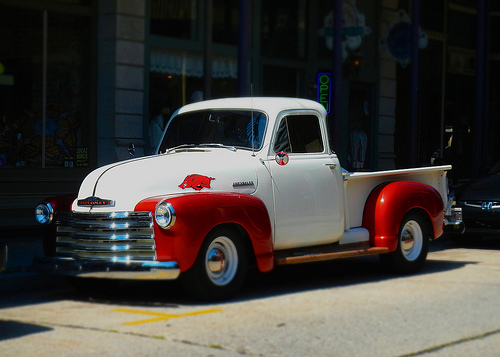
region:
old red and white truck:
[45, 68, 476, 304]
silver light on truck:
[147, 195, 172, 230]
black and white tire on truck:
[195, 208, 246, 294]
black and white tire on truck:
[392, 205, 429, 268]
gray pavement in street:
[298, 291, 456, 329]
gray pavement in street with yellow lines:
[61, 294, 271, 353]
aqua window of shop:
[8, 11, 110, 156]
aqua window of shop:
[142, 9, 269, 82]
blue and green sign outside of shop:
[318, 62, 341, 112]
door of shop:
[388, 38, 468, 158]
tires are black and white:
[184, 211, 262, 312]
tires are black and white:
[181, 222, 302, 332]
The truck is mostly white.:
[62, 168, 439, 231]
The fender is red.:
[161, 209, 244, 246]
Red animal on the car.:
[169, 163, 227, 199]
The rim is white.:
[212, 247, 247, 276]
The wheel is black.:
[198, 272, 235, 302]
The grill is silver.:
[73, 228, 135, 262]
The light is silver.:
[141, 200, 178, 230]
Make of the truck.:
[73, 193, 123, 213]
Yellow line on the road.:
[144, 308, 213, 328]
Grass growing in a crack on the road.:
[116, 330, 189, 349]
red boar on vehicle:
[169, 162, 234, 205]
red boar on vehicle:
[156, 140, 265, 265]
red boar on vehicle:
[161, 151, 207, 192]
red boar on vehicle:
[150, 150, 244, 214]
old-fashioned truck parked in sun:
[32, 37, 478, 322]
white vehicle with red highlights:
[32, 70, 469, 300]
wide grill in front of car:
[45, 207, 160, 267]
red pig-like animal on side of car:
[160, 155, 220, 190]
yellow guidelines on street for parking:
[86, 290, 236, 332]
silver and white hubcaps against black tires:
[195, 226, 245, 288]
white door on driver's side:
[255, 90, 370, 270]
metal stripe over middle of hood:
[72, 140, 207, 220]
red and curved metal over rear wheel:
[355, 165, 455, 265]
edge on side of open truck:
[340, 160, 460, 182]